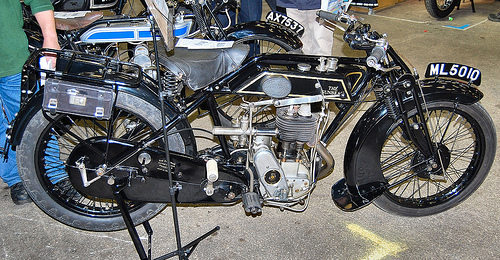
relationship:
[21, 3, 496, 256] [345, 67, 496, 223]
motorcycle has front tire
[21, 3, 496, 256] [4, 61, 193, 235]
motorcycle has back tire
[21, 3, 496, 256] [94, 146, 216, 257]
motorcycle has kickstand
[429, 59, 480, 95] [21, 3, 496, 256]
license plate on motorcycle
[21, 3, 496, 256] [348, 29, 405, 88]
motorcycle has handlebars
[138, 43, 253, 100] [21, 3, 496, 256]
seat on motorcycle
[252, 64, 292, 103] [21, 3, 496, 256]
gas tank on motorcycle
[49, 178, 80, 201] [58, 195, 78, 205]
boot has edge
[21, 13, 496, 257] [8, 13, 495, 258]
motorcycle parked on concrete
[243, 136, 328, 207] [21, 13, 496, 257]
has a motor on motorcycle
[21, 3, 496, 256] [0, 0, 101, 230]
motorcycle belongs to collector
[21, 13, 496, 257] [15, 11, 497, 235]
motorcycle part of collection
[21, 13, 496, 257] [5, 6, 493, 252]
motorcycle at museum